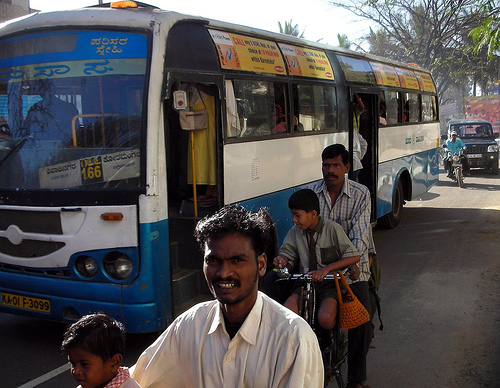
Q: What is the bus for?
A: Transportation.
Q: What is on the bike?
A: Orange bag.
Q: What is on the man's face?
A: Mustache.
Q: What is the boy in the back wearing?
A: Dress shirt and tie.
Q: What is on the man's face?
A: Facial hair.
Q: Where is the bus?
A: Street.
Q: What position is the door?
A: Open.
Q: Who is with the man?
A: Child.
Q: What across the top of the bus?
A: Advertisements.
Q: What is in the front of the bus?
A: Windshield.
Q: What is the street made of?
A: Concrete.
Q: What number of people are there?
A: Four.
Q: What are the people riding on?
A: Bikes.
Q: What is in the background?
A: Trees.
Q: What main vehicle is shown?
A: Bus.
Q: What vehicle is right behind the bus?
A: Motorcycle.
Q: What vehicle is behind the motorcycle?
A: Car.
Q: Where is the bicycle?
A: Next to the bus.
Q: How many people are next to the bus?
A: Four.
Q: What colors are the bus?
A: Blue and white.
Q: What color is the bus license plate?
A: Yellow.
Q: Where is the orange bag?
A: Bike handlebars.